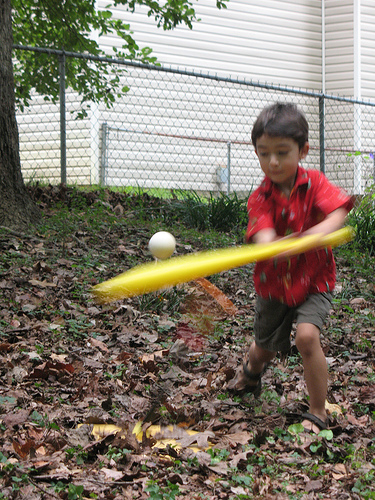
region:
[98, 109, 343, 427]
boy swinging a bat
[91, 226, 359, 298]
the bat is yellow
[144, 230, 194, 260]
ball is in midair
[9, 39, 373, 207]
fence behind the boy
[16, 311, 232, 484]
fallen leaves on the ground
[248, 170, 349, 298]
boy wearing red shirt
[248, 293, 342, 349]
boy wearing gray shorts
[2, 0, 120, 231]
tree growing beside the boy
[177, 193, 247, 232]
tall grass growing behind the boy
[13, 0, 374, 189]
house siding behind the boy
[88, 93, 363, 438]
a kid playing baseball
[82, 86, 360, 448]
boy hits a ball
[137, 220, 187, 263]
ball is color white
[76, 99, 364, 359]
boy holds a bat with two hands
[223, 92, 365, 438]
boy wears a red shirt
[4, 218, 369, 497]
dry leaves over the grass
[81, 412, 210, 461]
yellow leaves over the grass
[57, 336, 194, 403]
brown leaves over the grass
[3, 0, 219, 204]
a tree in front a home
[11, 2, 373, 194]
a white home behind a boy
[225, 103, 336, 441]
young boy in red shirt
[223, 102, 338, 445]
young boy playing baseball in leaves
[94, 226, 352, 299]
yellow plastic baseball bat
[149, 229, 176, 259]
white play baseball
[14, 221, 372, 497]
dead leaves on ground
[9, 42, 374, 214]
chain link fence near house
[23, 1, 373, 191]
side of white house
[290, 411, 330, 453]
child's sandal in leaves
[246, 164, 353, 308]
red shirt on child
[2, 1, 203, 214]
tree in yard where child is playing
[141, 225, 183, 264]
Round white ping pong ball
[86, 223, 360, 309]
Bright yellow bat in motion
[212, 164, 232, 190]
Small silver box on the side of the building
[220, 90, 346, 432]
Young boy holding a bat and hitting a ball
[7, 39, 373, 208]
Metal fence along the back of the yard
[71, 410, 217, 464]
Yellow object in the leaves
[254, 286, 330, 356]
Boy's dark grey shorts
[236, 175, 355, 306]
Bright red boy's shirt with pattern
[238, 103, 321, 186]
Boy's round head with dark hair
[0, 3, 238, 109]
Tree leaves hanging down in the background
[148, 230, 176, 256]
white plastic toy baseball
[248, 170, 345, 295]
red button down shirt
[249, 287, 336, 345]
grey cotton cargo shorts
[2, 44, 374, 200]
grey metal chain link fence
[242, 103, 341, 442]
boy playing baseball in yard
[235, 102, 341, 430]
boy wearing black candles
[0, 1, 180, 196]
tree with green leaves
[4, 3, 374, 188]
tan siding on house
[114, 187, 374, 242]
plants next to fence